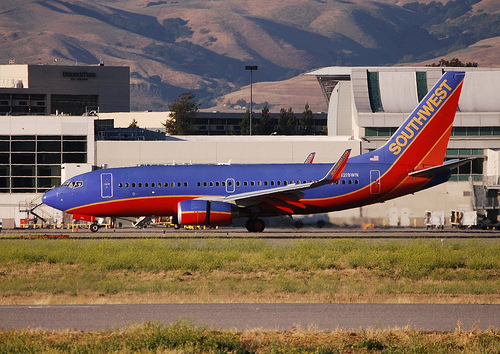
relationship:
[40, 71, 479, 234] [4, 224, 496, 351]
airplane on land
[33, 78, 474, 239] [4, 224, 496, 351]
airplane on land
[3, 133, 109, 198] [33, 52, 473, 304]
windows on building